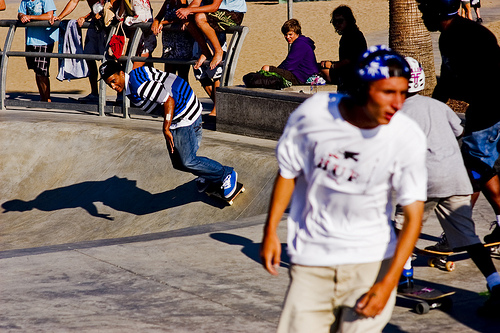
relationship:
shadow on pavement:
[1, 177, 242, 220] [59, 250, 117, 277]